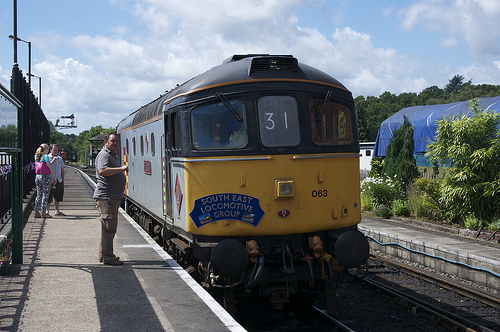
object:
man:
[91, 130, 130, 265]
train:
[113, 51, 372, 294]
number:
[263, 110, 290, 130]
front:
[180, 77, 365, 238]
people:
[45, 143, 68, 218]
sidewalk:
[0, 162, 248, 332]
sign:
[188, 192, 266, 229]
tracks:
[318, 309, 354, 332]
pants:
[94, 199, 123, 264]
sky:
[0, 0, 500, 136]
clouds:
[172, 56, 189, 57]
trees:
[382, 110, 424, 215]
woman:
[32, 142, 58, 219]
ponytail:
[35, 147, 44, 162]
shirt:
[92, 146, 127, 200]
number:
[311, 189, 328, 198]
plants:
[492, 181, 499, 224]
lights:
[25, 72, 43, 108]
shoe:
[103, 259, 126, 266]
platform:
[0, 160, 245, 331]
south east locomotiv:
[199, 194, 254, 218]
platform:
[358, 202, 500, 290]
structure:
[370, 94, 500, 182]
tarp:
[370, 94, 500, 169]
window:
[255, 94, 302, 147]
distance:
[0, 0, 499, 154]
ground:
[0, 158, 500, 332]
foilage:
[0, 72, 500, 233]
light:
[7, 34, 21, 42]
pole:
[26, 42, 33, 87]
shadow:
[15, 261, 166, 332]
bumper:
[191, 225, 372, 294]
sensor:
[276, 209, 291, 219]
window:
[308, 98, 355, 147]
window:
[187, 97, 249, 151]